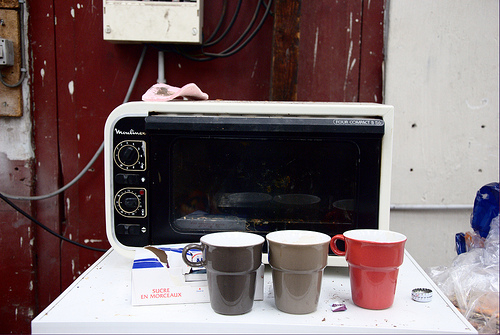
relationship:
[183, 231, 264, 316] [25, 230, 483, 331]
brown mug on dryer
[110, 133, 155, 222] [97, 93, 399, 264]
dials on oven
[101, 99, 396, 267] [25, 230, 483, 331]
microwave on dryer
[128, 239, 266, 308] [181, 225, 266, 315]
box near mugs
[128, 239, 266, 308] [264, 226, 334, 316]
box near mugs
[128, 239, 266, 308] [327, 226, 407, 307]
box near mugs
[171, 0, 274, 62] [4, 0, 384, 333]
cords on wall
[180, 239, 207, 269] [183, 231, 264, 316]
handle on brown mug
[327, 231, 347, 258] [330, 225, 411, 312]
handle on cup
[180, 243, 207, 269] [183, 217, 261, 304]
handle on brown mug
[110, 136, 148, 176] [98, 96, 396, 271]
knob on microwave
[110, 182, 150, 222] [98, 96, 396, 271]
knob on microwave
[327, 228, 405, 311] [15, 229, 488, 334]
cup on table.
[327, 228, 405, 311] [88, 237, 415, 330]
cup on table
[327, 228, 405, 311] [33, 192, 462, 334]
cup on table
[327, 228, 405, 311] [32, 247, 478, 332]
cup on table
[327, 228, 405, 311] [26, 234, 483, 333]
cup on table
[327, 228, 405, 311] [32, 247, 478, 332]
cup on edge of table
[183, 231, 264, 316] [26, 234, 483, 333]
brown mug on table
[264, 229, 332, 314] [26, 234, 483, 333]
coffee cups on table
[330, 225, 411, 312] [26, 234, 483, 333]
cup on table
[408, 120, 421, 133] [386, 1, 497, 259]
hole drilled into wall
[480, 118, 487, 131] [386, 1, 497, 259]
hole drilled into wall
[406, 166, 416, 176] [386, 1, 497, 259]
hole drilled into wall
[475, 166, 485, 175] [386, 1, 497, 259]
hole drilled into wall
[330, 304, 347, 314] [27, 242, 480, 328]
granules spilled on table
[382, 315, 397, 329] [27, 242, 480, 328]
granules spilled on table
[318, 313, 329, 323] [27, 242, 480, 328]
granules spilled on table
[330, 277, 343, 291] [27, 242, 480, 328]
granules spilled on table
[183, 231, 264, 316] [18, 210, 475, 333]
brown mug on top of counter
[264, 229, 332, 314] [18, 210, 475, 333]
coffee cups on top of counter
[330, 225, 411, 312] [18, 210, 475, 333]
cup on top of counter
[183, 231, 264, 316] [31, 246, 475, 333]
brown mug on top of counter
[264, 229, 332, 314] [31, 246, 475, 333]
coffee cups on top of counter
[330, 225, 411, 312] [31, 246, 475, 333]
cup on top of counter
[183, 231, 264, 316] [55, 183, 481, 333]
brown mug on counter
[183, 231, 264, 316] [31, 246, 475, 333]
brown mug on counter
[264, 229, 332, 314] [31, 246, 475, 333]
coffee cups on counter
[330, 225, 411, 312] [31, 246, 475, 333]
cup on counter